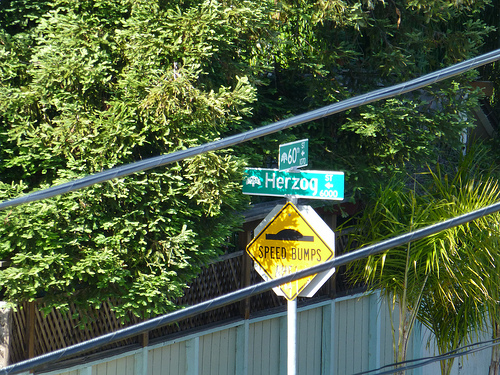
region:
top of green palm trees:
[404, 198, 486, 340]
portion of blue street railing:
[169, 275, 359, 298]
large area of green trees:
[51, 45, 249, 121]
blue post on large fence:
[308, 296, 356, 360]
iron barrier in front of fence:
[63, 269, 242, 308]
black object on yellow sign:
[257, 228, 337, 247]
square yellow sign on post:
[230, 205, 340, 298]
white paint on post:
[270, 290, 315, 355]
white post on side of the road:
[240, 201, 345, 362]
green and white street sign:
[233, 133, 370, 208]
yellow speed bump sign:
[244, 199, 356, 319]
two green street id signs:
[227, 143, 379, 213]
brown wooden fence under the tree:
[21, 270, 248, 341]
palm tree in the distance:
[379, 160, 487, 368]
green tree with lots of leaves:
[27, 23, 226, 141]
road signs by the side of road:
[29, 20, 447, 334]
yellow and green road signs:
[188, 104, 385, 357]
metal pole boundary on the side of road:
[20, 184, 99, 196]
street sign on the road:
[231, 138, 373, 213]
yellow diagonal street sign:
[237, 202, 345, 299]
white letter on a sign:
[305, 173, 320, 198]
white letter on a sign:
[297, 174, 312, 192]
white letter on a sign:
[289, 174, 301, 190]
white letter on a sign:
[282, 172, 292, 193]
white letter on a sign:
[273, 173, 285, 192]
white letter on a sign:
[263, 169, 278, 191]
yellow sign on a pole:
[239, 200, 336, 302]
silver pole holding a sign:
[280, 295, 302, 373]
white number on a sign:
[284, 145, 295, 167]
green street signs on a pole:
[235, 126, 359, 211]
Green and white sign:
[269, 135, 320, 169]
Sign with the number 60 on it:
[270, 138, 315, 168]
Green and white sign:
[237, 166, 349, 200]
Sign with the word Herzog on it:
[238, 164, 350, 202]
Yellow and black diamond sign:
[243, 199, 335, 301]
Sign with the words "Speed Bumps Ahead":
[238, 204, 336, 302]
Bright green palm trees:
[342, 141, 497, 373]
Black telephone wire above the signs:
[0, 40, 497, 228]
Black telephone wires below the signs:
[2, 191, 498, 373]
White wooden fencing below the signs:
[40, 269, 499, 373]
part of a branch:
[168, 245, 183, 263]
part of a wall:
[238, 331, 248, 355]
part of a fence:
[146, 248, 158, 263]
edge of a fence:
[231, 338, 235, 346]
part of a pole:
[283, 320, 302, 329]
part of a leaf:
[53, 162, 57, 171]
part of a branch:
[133, 225, 149, 235]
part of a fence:
[353, 347, 358, 357]